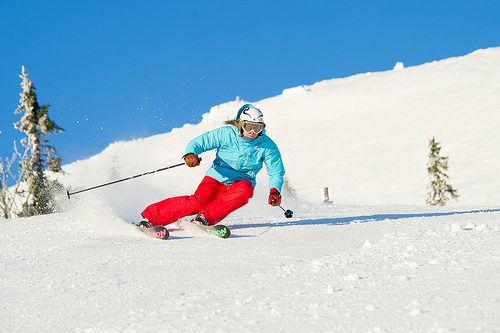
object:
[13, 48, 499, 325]
snow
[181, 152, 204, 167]
mitten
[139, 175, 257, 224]
pants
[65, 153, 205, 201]
pole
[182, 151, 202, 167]
hand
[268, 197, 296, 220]
pole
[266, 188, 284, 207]
hand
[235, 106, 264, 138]
helmet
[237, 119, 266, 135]
goggles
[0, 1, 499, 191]
sky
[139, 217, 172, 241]
ski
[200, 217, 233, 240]
ski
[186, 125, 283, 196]
coat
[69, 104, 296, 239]
woman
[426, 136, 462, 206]
tree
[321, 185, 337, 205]
marker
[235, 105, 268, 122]
patterns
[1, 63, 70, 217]
pine tree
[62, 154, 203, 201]
ski poles